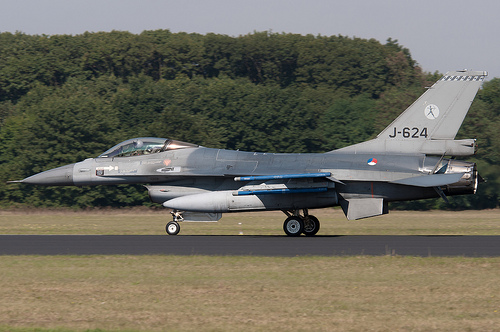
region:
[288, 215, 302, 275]
There are small black tires here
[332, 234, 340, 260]
There is a patch of black asphalt here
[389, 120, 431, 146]
This plane says J-624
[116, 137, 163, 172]
There is a glass cockpit here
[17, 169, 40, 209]
There is a dark gray front to the plane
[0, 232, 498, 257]
black asphalt runway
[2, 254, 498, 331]
grassy area beside a runway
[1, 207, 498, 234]
grassy area beside a runway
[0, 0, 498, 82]
drak grey sky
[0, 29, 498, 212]
trees standing beside a runway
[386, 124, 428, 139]
identification number on plane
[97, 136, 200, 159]
window over cockpit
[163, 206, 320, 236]
landing gear on a plane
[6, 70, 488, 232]
plane on a runway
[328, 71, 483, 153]
grey tail on a plane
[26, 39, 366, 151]
Trees on the side of the runway.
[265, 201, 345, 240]
Wheels on the plane.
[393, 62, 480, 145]
The tail of the plane.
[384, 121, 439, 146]
Numbers on the tail of the plane.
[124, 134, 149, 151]
Pilot on the plane.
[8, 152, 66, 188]
The nose of the plane is pointy.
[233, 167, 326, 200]
Wing on the plane.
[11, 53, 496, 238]
airplane on the runway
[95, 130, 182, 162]
windows around the cockpit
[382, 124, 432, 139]
black writing on the tail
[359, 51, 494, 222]
tail of the plane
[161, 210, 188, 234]
front wheel is down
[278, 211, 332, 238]
a pair of wheels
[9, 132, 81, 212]
nose of the plane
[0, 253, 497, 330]
grass on the ground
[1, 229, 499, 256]
runway is made of asphalt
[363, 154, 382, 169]
red, white, and blue circle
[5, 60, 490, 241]
A fighter jet on a runway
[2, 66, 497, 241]
A fighter jet on a runway